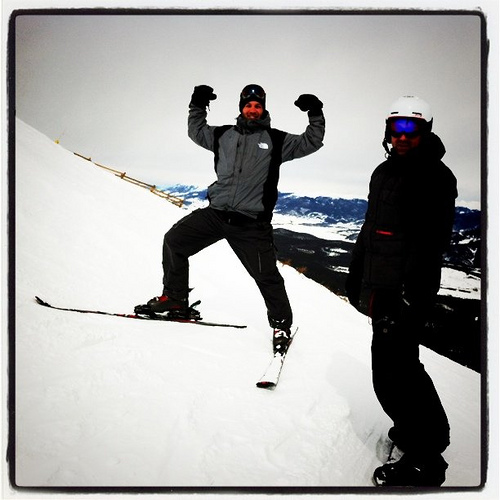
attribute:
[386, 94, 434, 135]
helmet — white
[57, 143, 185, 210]
fence — brown, wood, small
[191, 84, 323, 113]
gloves — black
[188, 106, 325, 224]
jacket — black, grey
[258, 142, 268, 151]
logo — white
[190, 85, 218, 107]
glove — black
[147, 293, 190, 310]
boot — red, black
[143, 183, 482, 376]
mountains — far away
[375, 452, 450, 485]
boot — black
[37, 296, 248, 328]
ski — black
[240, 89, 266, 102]
goggles — black